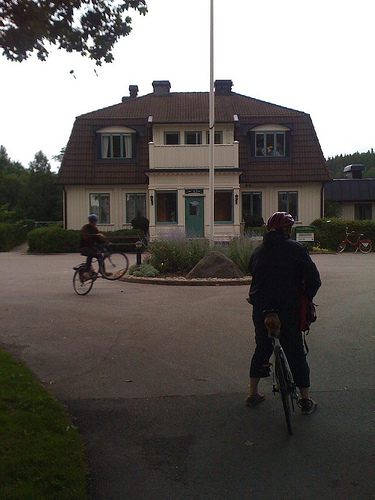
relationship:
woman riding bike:
[230, 197, 333, 422] [263, 311, 312, 439]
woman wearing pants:
[230, 197, 333, 422] [238, 298, 316, 397]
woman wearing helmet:
[230, 197, 333, 422] [259, 203, 300, 243]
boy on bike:
[67, 205, 121, 283] [71, 248, 133, 315]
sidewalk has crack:
[15, 246, 350, 500] [69, 362, 264, 459]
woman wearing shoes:
[230, 197, 333, 422] [232, 386, 324, 420]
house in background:
[49, 51, 330, 231] [5, 1, 374, 269]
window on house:
[153, 189, 183, 228] [49, 51, 330, 231]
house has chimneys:
[49, 51, 330, 231] [118, 71, 238, 100]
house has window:
[49, 51, 330, 231] [153, 189, 183, 228]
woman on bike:
[230, 197, 333, 422] [263, 311, 312, 439]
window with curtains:
[153, 189, 183, 228] [96, 133, 135, 159]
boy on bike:
[67, 205, 121, 283] [263, 311, 312, 439]